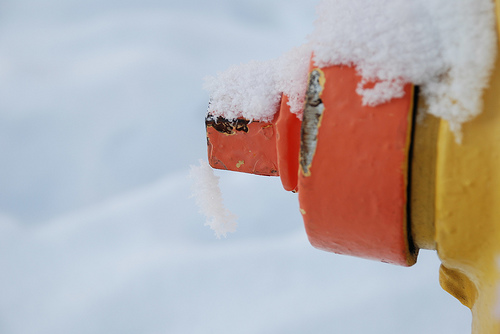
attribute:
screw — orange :
[205, 46, 302, 202]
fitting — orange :
[297, 13, 475, 293]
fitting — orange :
[297, 14, 423, 294]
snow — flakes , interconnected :
[193, 156, 229, 246]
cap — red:
[196, 30, 302, 190]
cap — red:
[191, 36, 422, 262]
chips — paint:
[278, 68, 323, 183]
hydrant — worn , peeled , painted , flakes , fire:
[198, 25, 496, 332]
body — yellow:
[414, 31, 496, 332]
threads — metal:
[407, 80, 431, 250]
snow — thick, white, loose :
[7, 3, 497, 333]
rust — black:
[206, 114, 248, 137]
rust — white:
[298, 74, 322, 169]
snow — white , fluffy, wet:
[205, 0, 494, 149]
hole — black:
[206, 118, 248, 134]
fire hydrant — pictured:
[199, 25, 493, 332]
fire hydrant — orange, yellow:
[206, 0, 497, 330]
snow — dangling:
[187, 156, 233, 240]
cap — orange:
[180, 30, 411, 268]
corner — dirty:
[435, 263, 478, 311]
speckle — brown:
[313, 94, 322, 107]